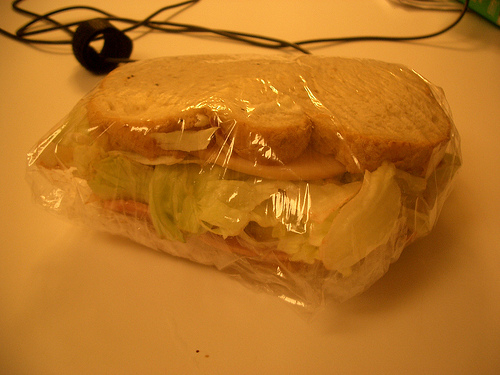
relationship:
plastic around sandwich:
[23, 43, 466, 317] [42, 48, 452, 285]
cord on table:
[44, 12, 464, 65] [10, 8, 492, 374]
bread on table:
[99, 52, 435, 163] [37, 27, 497, 337]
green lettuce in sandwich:
[45, 143, 463, 278] [42, 48, 452, 285]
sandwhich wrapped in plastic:
[32, 52, 463, 305] [23, 43, 466, 317]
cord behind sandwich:
[0, 0, 469, 64] [42, 48, 452, 285]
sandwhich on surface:
[32, 52, 463, 305] [2, 1, 498, 372]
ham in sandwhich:
[283, 162, 355, 187] [32, 52, 463, 305]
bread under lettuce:
[93, 204, 223, 277] [78, 142, 410, 263]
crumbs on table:
[180, 347, 213, 359] [10, 8, 492, 374]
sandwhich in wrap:
[32, 52, 463, 305] [21, 50, 466, 317]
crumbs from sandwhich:
[170, 335, 222, 372] [32, 52, 463, 305]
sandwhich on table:
[32, 52, 463, 305] [10, 8, 492, 374]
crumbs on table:
[170, 335, 222, 372] [10, 8, 492, 374]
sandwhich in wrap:
[107, 50, 448, 308] [21, 50, 466, 317]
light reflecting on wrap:
[26, 52, 463, 325] [21, 50, 466, 317]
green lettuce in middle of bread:
[45, 143, 463, 278] [93, 48, 456, 163]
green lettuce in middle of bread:
[45, 143, 463, 278] [184, 65, 403, 167]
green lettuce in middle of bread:
[45, 143, 463, 278] [86, 50, 457, 294]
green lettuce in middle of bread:
[45, 143, 463, 278] [121, 67, 441, 151]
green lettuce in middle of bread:
[45, 110, 409, 272] [93, 48, 456, 163]